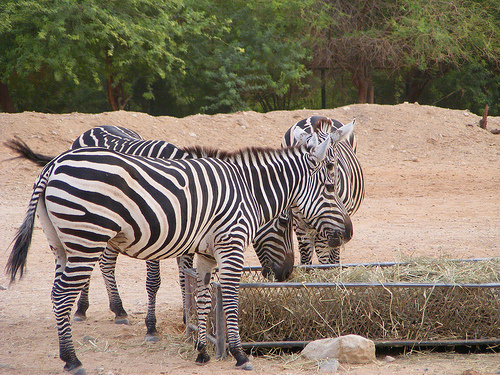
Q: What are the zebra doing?
A: Eating.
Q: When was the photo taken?
A: During the day.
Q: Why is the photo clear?
A: Its during the day.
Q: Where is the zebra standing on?
A: The ground.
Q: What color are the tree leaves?
A: Green.